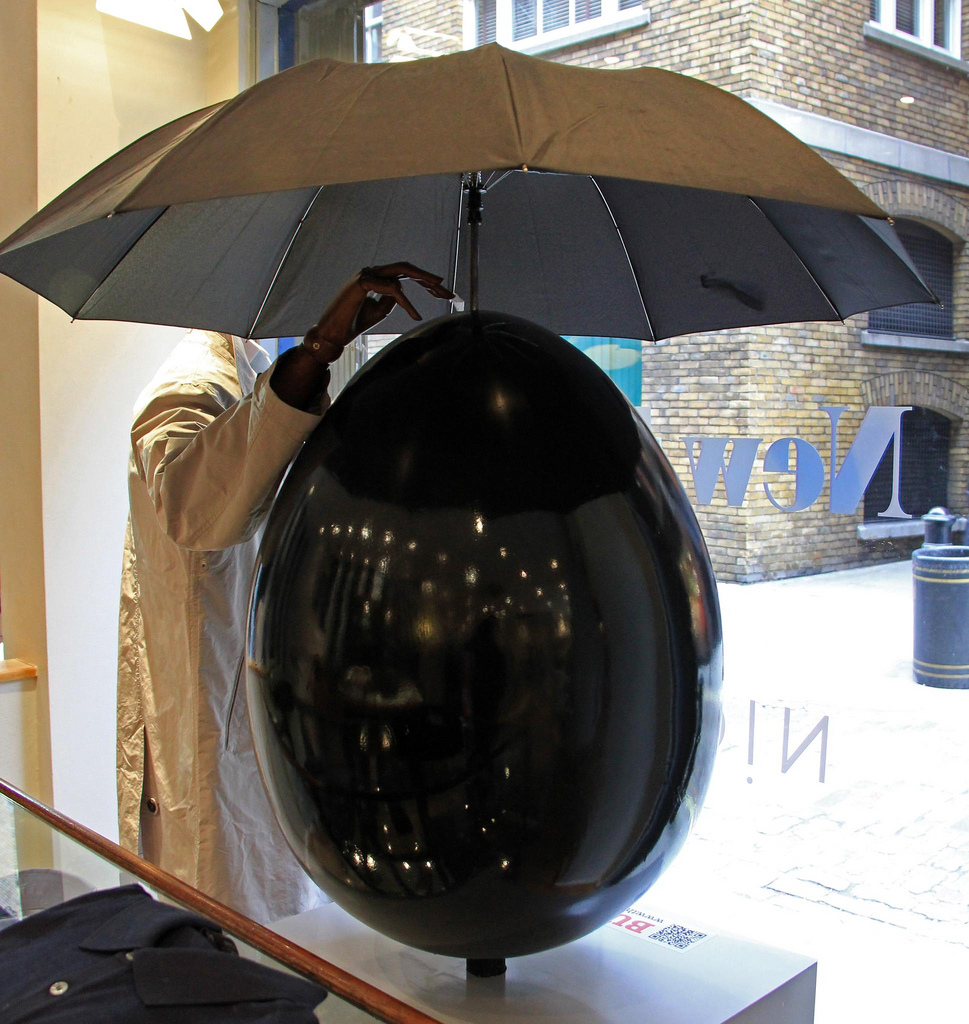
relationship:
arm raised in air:
[142, 243, 453, 560] [21, 10, 903, 270]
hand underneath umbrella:
[303, 262, 458, 364] [114, 109, 751, 304]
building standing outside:
[362, 3, 932, 582] [359, 1, 922, 1021]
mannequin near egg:
[116, 262, 459, 925] [264, 346, 688, 959]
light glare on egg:
[388, 849, 424, 882] [244, 310, 726, 961]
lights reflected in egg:
[324, 492, 581, 625] [203, 277, 766, 985]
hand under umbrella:
[197, 254, 505, 359] [0, 13, 963, 361]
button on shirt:
[46, 971, 74, 999] [8, 858, 333, 1023]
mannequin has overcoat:
[110, 229, 444, 961] [108, 248, 448, 933]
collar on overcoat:
[201, 338, 282, 417] [115, 247, 333, 931]